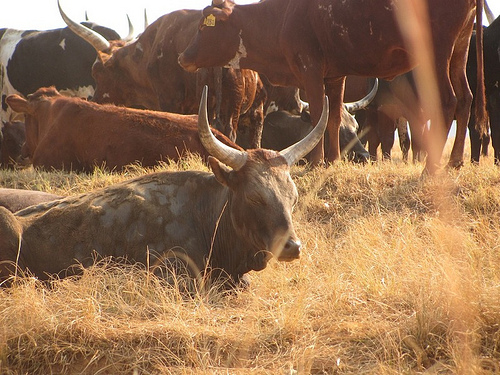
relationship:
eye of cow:
[196, 21, 208, 29] [197, 0, 471, 157]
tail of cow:
[470, 37, 489, 100] [197, 0, 471, 157]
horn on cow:
[79, 21, 104, 50] [197, 0, 471, 157]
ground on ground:
[0, 225, 499, 375] [208, 343, 247, 364]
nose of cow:
[176, 53, 184, 68] [197, 0, 471, 157]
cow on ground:
[197, 0, 471, 157] [208, 343, 247, 364]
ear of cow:
[217, 4, 227, 20] [197, 0, 471, 157]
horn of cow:
[79, 21, 104, 50] [197, 0, 471, 157]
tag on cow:
[199, 14, 218, 33] [197, 0, 471, 157]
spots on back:
[326, 10, 345, 22] [296, 2, 317, 9]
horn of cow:
[55, 0, 110, 53] [197, 0, 471, 157]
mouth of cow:
[269, 245, 290, 255] [197, 0, 471, 157]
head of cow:
[137, 0, 248, 75] [197, 0, 471, 157]